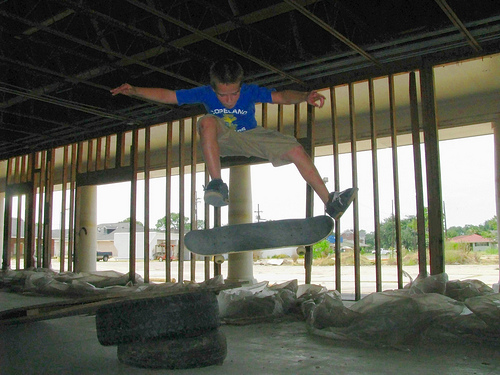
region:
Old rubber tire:
[94, 286, 230, 350]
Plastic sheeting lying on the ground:
[298, 280, 498, 359]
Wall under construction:
[362, 72, 429, 300]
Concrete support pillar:
[223, 161, 263, 293]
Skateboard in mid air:
[180, 213, 340, 266]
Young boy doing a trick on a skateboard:
[102, 50, 364, 274]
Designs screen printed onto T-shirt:
[210, 105, 254, 136]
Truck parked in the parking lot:
[87, 243, 122, 261]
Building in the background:
[447, 228, 498, 255]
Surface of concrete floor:
[250, 333, 310, 373]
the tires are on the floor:
[91, 282, 232, 373]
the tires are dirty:
[82, 287, 230, 372]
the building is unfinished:
[1, 0, 499, 373]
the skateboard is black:
[179, 211, 337, 263]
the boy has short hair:
[206, 57, 246, 94]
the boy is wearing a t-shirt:
[171, 81, 279, 136]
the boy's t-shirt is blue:
[173, 82, 277, 135]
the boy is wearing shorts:
[193, 112, 307, 170]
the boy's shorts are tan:
[193, 110, 304, 172]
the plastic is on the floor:
[0, 262, 499, 368]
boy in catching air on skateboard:
[100, 57, 381, 265]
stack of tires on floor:
[77, 283, 239, 368]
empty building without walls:
[12, 132, 492, 353]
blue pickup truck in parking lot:
[67, 245, 114, 265]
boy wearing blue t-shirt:
[105, 58, 332, 122]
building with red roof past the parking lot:
[433, 229, 498, 258]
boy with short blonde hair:
[190, 54, 262, 114]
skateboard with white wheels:
[172, 215, 352, 265]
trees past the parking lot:
[367, 206, 449, 264]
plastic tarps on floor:
[248, 258, 495, 360]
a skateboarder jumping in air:
[103, 57, 354, 261]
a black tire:
[99, 294, 220, 345]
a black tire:
[112, 332, 234, 369]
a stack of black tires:
[94, 283, 226, 364]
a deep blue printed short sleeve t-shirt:
[171, 81, 277, 132]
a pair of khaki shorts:
[189, 115, 299, 168]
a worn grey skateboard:
[179, 211, 337, 261]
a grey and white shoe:
[322, 182, 359, 221]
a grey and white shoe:
[201, 177, 230, 207]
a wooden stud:
[418, 64, 446, 282]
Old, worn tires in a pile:
[92, 291, 227, 368]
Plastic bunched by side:
[226, 280, 496, 342]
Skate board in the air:
[178, 214, 338, 254]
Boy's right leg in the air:
[192, 117, 228, 207]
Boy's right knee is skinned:
[195, 112, 209, 139]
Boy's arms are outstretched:
[96, 77, 336, 112]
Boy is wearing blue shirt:
[181, 92, 271, 135]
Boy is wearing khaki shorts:
[196, 113, 298, 172]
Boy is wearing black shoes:
[201, 180, 360, 220]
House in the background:
[442, 222, 494, 265]